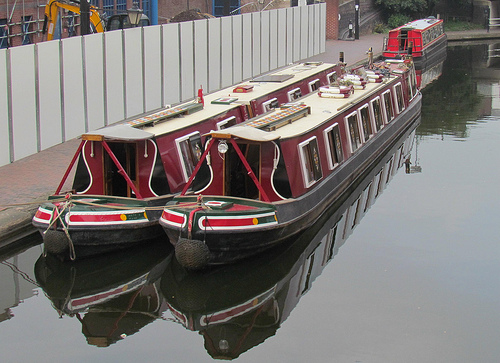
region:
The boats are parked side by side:
[25, 73, 401, 348]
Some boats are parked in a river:
[16, 40, 496, 302]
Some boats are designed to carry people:
[10, 45, 472, 322]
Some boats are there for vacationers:
[11, 76, 461, 321]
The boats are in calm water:
[10, 90, 466, 307]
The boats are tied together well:
[7, 60, 387, 306]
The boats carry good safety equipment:
[11, 65, 422, 335]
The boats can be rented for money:
[35, 60, 381, 313]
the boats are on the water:
[39, 50, 419, 252]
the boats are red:
[38, 51, 422, 248]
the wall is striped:
[1, 3, 326, 168]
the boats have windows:
[294, 73, 417, 183]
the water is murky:
[3, 37, 498, 359]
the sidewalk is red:
[4, 26, 391, 224]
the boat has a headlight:
[219, 143, 228, 152]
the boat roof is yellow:
[94, 62, 407, 142]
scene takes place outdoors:
[0, 0, 499, 361]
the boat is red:
[388, 17, 443, 62]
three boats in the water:
[43, 0, 463, 305]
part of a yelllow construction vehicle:
[34, 2, 97, 49]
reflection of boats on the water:
[45, 52, 451, 362]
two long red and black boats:
[78, 53, 436, 280]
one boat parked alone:
[374, 16, 476, 83]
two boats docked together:
[28, 44, 455, 359]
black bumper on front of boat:
[153, 215, 231, 287]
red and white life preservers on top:
[303, 63, 402, 113]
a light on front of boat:
[211, 139, 233, 158]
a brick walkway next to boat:
[6, 41, 379, 223]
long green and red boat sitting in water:
[159, 54, 427, 266]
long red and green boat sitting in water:
[27, 59, 349, 254]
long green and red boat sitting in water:
[382, 13, 454, 64]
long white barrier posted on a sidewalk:
[0, 3, 327, 168]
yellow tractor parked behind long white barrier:
[39, 0, 146, 37]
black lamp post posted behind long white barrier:
[124, 1, 143, 26]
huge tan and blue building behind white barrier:
[0, 0, 266, 45]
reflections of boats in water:
[10, 125, 429, 359]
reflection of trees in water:
[411, 48, 479, 121]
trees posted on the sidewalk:
[376, 0, 436, 40]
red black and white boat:
[160, 58, 426, 265]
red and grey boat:
[384, 17, 448, 61]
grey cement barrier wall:
[1, 4, 330, 168]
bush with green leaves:
[376, 0, 426, 29]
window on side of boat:
[348, 113, 361, 154]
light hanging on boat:
[218, 141, 228, 154]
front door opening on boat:
[222, 142, 261, 202]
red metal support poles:
[56, 139, 141, 201]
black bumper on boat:
[175, 235, 209, 274]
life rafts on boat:
[318, 79, 355, 102]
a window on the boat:
[298, 144, 323, 176]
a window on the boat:
[323, 132, 336, 152]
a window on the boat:
[357, 107, 382, 134]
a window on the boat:
[380, 90, 391, 111]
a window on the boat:
[391, 82, 414, 110]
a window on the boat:
[172, 136, 193, 166]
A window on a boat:
[302, 138, 324, 182]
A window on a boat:
[323, 126, 343, 165]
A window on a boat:
[359, 105, 371, 139]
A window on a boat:
[373, 100, 382, 125]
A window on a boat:
[382, 90, 393, 117]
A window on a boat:
[392, 83, 403, 106]